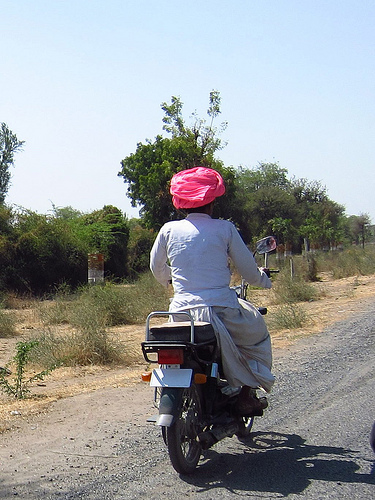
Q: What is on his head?
A: Turban.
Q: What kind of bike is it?
A: Motorbike.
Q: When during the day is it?
A: Daytime.